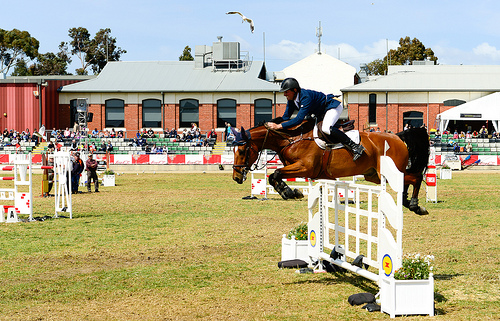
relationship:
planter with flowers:
[371, 240, 453, 318] [361, 234, 491, 312]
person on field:
[85, 153, 102, 193] [1, 172, 498, 319]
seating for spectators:
[1, 125, 498, 169] [1, 123, 499, 173]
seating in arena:
[1, 125, 498, 169] [2, 63, 499, 186]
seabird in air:
[228, 0, 261, 36] [5, 5, 498, 71]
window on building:
[254, 100, 271, 117] [53, 90, 470, 145]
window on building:
[141, 98, 165, 129] [62, 35, 289, 159]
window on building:
[141, 98, 165, 129] [54, 40, 287, 141]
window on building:
[105, 98, 125, 127] [354, 84, 444, 137]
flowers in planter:
[392, 249, 437, 279] [378, 272, 434, 319]